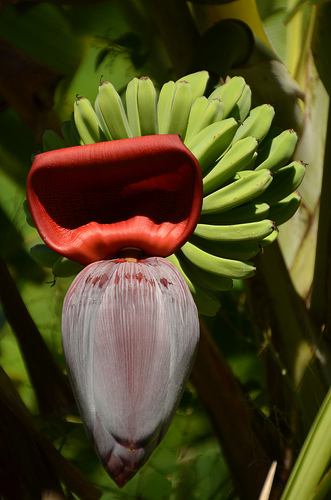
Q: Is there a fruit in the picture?
A: Yes, there is a fruit.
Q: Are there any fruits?
A: Yes, there is a fruit.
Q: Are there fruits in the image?
A: Yes, there is a fruit.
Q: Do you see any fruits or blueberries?
A: Yes, there is a fruit.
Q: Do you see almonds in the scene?
A: No, there are no almonds.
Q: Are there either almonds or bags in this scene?
A: No, there are no almonds or bags.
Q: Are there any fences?
A: No, there are no fences.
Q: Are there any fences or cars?
A: No, there are no fences or cars.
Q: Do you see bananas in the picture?
A: Yes, there is a banana.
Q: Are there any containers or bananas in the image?
A: Yes, there is a banana.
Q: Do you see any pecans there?
A: No, there are no pecans.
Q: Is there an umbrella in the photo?
A: No, there are no umbrellas.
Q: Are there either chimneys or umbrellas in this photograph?
A: No, there are no umbrellas or chimneys.